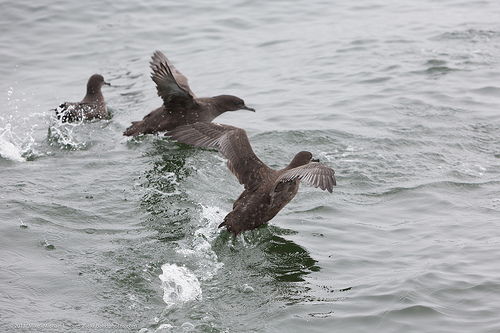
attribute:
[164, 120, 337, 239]
bird — about to fly, making waves, brown, brownish-gray, splashing, here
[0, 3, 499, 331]
water — in motion, gray, white, splashing, moved, blue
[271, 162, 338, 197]
wing — grey, outstretched, stretched out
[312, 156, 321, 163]
beak — curved, here, sharp, long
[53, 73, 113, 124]
bird — sitting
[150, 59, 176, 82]
feathers — brown